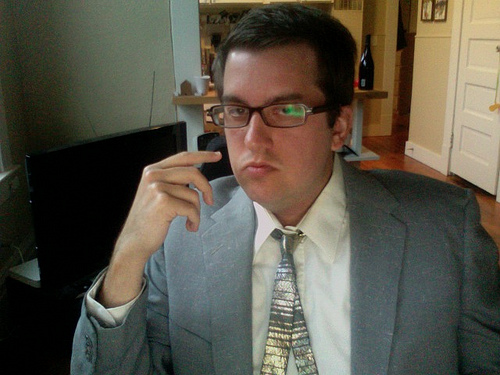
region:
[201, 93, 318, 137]
black glasses worn by man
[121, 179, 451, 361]
man wearing gray suit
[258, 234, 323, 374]
man wearing silver tie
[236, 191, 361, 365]
man wearing white shirt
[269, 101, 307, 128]
reflection in eye glasses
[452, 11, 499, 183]
white door in room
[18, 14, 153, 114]
tan wall in room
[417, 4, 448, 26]
picture in room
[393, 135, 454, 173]
white base board in room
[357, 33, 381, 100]
black shiny bottle on table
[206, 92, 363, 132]
A PAIR OF GLASSES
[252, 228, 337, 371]
A SILVER NECK TIE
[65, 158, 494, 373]
A MANS GRAY SUIT COAT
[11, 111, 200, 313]
A FLAT SCREEN TV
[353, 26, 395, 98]
A BLACK BOTTLE OF WINE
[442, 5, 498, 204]
A WHITE WOODEN DOOR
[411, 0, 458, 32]
TWO PICTURES ON THE WALL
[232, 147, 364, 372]
A WHITE MANS DRESS SHIRT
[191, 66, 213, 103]
A WHITE FOAM CUP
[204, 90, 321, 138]
A REFLECTION IN THE MANS GLASSES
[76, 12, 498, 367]
a man thinking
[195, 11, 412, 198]
a wine bottle is behind the man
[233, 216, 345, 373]
the tie is shiny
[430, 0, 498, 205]
the door is white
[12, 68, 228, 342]
a TV is behind the man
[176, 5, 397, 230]
the man has short brown hair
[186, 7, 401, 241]
the man is wearing dark colored glasses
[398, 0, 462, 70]
two pictures hang on the wall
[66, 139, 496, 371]
the man's suit is gray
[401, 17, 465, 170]
the wall is yellow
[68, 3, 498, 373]
man in grey suit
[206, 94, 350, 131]
black glasses on man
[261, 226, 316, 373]
a shiny, unkempt tie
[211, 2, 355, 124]
well-groomed hair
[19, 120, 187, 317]
a television behind the man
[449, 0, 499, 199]
a closed, white door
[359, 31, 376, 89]
a bottle of wine on the counter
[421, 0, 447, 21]
pictures hanging by the door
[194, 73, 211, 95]
a paper cup behind the man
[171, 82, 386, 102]
a wooden counter behind the man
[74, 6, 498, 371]
man staring at the camera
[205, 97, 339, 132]
man's pair of eyeglasses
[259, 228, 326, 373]
silver necktie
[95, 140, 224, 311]
man's right hand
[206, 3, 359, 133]
a man's dark colored hair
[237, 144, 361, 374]
collared white colored buttoned down shirt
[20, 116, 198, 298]
flat screen television monitor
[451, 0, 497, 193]
white paneled door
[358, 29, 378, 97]
dark colored glass bottle on a shelf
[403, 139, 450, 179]
white base board